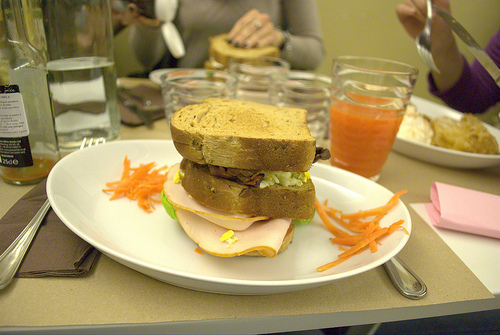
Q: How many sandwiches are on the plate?
A: One.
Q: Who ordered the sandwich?
A: A customer.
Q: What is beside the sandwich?
A: Carrots.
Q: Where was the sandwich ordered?
A: A restaurant.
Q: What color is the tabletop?
A: Beige.